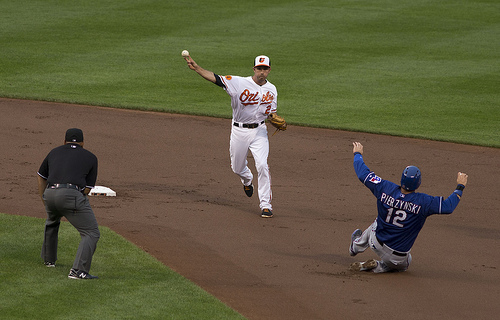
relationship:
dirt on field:
[139, 135, 257, 265] [106, 15, 163, 82]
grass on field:
[114, 15, 201, 89] [106, 15, 163, 82]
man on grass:
[23, 108, 135, 284] [114, 15, 201, 89]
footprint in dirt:
[327, 262, 375, 297] [139, 135, 257, 265]